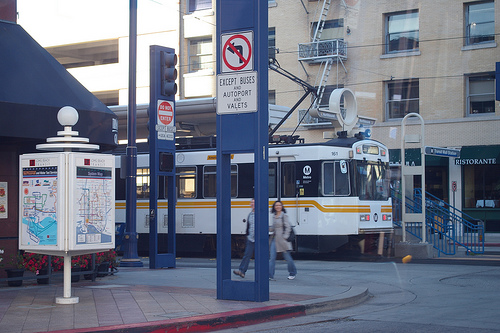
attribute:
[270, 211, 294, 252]
jacket — beige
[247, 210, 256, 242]
shirt — plaid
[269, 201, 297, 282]
woman — walking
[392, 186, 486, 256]
rails — blue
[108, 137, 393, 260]
tram — white, orange, here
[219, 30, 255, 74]
sign — red, black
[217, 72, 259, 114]
sign — white, black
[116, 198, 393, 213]
stripe — orange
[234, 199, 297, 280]
people — walking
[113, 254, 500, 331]
road — grey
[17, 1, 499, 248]
building — tan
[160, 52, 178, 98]
traffic light — black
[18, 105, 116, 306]
directory — white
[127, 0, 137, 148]
pole — black, metal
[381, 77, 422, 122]
window — glass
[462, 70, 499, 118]
window — glass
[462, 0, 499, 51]
window — glass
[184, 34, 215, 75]
window — glass, here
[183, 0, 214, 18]
window — glass, here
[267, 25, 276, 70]
window — glass, here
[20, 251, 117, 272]
flowers — red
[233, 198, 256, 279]
man — walking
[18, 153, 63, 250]
map — elevated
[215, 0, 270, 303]
frame — blue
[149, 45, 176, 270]
frame — blue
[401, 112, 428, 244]
bar — curved